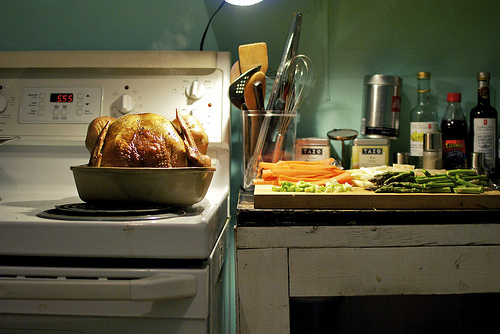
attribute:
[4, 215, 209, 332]
oven — white, dirty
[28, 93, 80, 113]
lights — red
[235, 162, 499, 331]
table — white, wooden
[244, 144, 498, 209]
chopping board — large, wooden, rectangular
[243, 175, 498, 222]
board — cutting board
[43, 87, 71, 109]
time — 5:55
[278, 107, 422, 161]
container — metal, square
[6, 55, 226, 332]
stove — white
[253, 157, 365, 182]
carrots — sliced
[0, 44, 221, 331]
oven — white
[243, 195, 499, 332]
table — white, wooden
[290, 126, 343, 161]
container — square, metal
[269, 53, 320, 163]
whisk — metal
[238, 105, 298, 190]
utensil holder — glass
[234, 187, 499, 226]
top — black